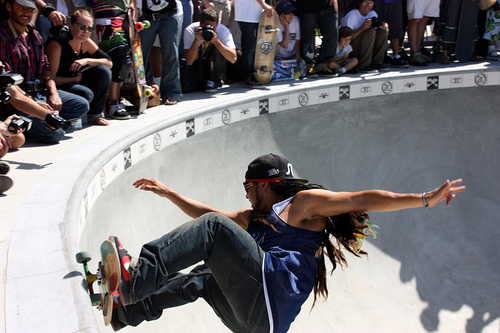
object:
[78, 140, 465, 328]
skateboarder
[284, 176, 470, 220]
arms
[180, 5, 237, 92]
man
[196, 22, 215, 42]
camera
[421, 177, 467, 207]
hand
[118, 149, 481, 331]
person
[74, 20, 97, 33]
sunglasses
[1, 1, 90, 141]
people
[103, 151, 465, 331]
skater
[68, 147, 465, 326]
man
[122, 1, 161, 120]
skateboard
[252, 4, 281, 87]
skateboard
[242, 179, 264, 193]
glasses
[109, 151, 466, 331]
skateboarder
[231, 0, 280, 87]
person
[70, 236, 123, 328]
skateboard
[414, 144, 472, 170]
ground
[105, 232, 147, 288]
shoes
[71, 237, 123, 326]
wheel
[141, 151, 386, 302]
man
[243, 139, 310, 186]
hat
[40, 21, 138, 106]
woman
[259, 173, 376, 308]
long hair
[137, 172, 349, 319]
man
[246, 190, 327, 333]
jersey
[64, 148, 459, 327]
skater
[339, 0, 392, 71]
man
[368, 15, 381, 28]
camera